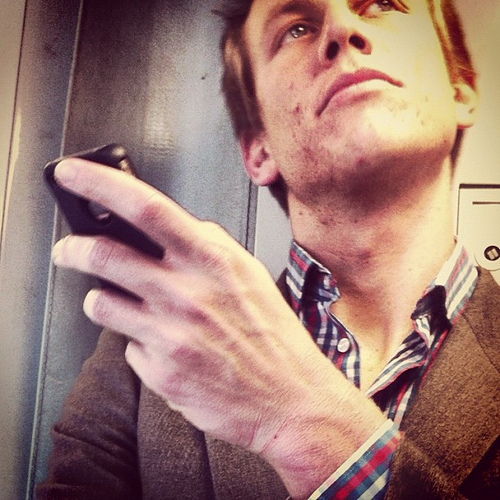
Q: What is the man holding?
A: A phone.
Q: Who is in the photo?
A: A man.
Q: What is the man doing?
A: Looking past camera.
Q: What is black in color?
A: The phone.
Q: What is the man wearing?
A: Shirt.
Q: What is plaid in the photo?
A: The shirt.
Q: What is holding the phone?
A: The hand.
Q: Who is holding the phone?
A: The man.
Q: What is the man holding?
A: Phone.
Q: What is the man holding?
A: Phone.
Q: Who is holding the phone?
A: The man.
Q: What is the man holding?
A: Phone.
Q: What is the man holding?
A: Phone.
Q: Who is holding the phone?
A: The man.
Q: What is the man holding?
A: Phone.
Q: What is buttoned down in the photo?
A: Shirt.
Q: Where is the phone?
A: In the man's hand.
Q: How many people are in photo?
A: One.